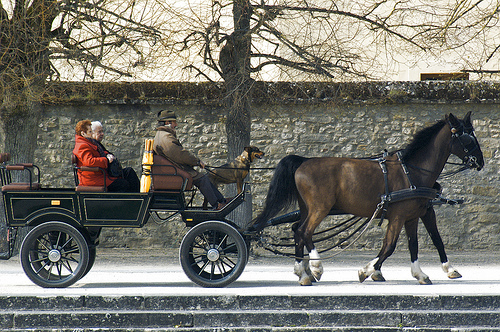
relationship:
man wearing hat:
[90, 109, 129, 164] [156, 105, 187, 123]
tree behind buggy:
[203, 5, 294, 159] [21, 196, 259, 281]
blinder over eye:
[454, 121, 476, 138] [463, 141, 472, 151]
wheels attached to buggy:
[163, 221, 252, 291] [21, 196, 259, 281]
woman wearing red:
[47, 106, 140, 201] [75, 174, 104, 187]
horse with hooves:
[254, 101, 482, 278] [287, 247, 328, 292]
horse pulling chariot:
[254, 101, 482, 278] [152, 177, 304, 293]